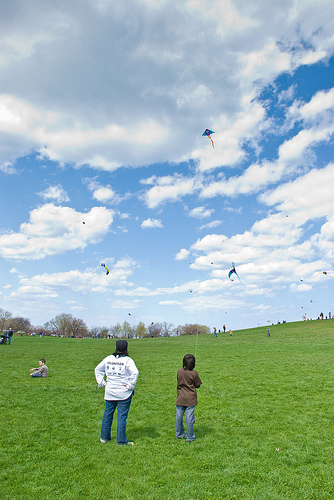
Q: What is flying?
A: Kites.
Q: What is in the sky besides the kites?
A: Clouds.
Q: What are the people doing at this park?
A: Flying kites.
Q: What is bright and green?
A: Grass.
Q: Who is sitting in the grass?
A: Boy.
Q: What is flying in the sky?
A: Kites.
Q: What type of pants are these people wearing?
A: Jeans.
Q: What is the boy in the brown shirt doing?
A: Flying a kite.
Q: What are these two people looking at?
A: The kites.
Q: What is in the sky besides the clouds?
A: Kites.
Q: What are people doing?
A: Flying kites.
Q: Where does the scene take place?
A: On a grassy field.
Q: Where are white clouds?
A: In the sky.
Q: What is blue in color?
A: The sky.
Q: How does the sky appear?
A: Cloudy.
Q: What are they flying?
A: Kites.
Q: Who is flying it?
A: People.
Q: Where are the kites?
A: In the air.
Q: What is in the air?
A: Kites.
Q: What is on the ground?
A: People.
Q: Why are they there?
A: To play.